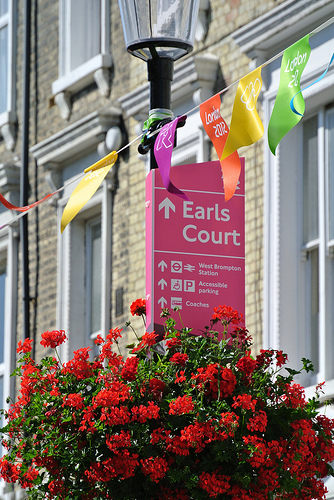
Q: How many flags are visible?
A: Six.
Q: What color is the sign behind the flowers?
A: Pink.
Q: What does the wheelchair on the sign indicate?
A: Wheelchair accessible.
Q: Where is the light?
A: Above the flags.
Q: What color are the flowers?
A: Red.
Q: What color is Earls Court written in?
A: White.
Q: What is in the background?
A: Building.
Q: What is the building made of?
A: Brick.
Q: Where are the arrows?
A: On the pink sign.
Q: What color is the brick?
A: Tan.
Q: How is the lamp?
A: Unlit.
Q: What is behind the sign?
A: Flowers.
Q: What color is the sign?
A: Pink.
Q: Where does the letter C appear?
A: On the sign.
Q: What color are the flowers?
A: Red.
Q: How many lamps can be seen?
A: One.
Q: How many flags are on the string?
A: Six.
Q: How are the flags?
A: Blowing in the breeze.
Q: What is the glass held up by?
A: Metal pole.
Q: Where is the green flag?
A: To the right.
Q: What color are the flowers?
A: Red.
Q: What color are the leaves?
A: Green.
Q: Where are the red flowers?
A: Next to the green leaves.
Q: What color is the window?
A: White.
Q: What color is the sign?
A: Pink and white.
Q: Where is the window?
A: On the building.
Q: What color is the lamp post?
A: Black.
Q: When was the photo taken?
A: Daytime.